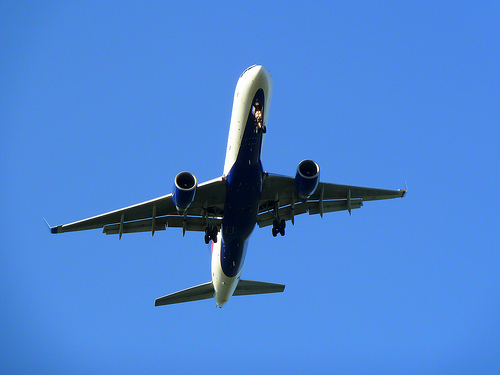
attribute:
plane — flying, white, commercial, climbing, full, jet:
[42, 63, 406, 307]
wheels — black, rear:
[272, 219, 288, 238]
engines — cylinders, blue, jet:
[172, 172, 198, 218]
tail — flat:
[157, 279, 288, 308]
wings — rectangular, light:
[44, 159, 406, 245]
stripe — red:
[208, 240, 214, 260]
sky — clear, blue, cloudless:
[2, 2, 500, 372]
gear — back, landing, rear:
[202, 207, 222, 227]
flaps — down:
[101, 216, 223, 239]